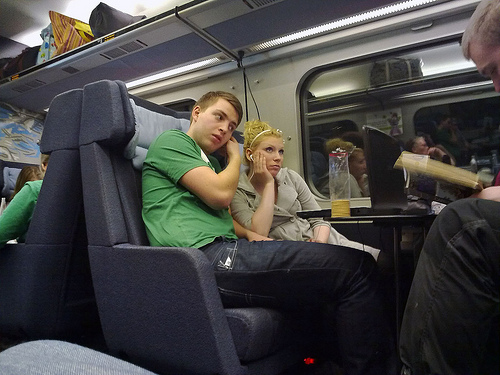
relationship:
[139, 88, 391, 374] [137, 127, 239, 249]
guy wearing shirt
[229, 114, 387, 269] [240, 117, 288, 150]
woman with hair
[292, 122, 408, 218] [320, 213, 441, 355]
laptop on table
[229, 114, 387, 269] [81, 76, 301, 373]
woman in seat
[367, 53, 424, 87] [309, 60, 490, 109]
duffle bag on shelf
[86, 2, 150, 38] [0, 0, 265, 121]
bag on shelf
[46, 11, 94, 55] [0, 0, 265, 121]
bag on shelf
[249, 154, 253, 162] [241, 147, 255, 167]
ear bud in ear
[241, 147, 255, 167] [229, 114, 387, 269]
ear of woman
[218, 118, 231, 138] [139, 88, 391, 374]
nose on guy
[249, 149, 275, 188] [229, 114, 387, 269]
right hand of woman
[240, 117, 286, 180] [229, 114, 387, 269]
head of woman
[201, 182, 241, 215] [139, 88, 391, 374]
right elbow of guy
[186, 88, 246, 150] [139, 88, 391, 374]
head of guy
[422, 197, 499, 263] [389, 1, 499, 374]
left knee of man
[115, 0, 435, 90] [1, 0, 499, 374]
overhead light on train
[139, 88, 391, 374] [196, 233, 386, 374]
guy wearing blue jeans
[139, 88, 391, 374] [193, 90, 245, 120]
guy has hair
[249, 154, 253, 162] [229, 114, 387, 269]
ear bud on woman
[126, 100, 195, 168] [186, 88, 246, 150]
cushion for head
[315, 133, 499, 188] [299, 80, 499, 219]
reflection in window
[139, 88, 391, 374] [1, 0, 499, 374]
guy on train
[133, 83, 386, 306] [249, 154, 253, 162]
couple sharing ear bud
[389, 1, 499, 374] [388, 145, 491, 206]
man reading book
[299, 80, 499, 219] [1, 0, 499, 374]
window on train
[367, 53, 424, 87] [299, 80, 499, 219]
duffle bag reflected in window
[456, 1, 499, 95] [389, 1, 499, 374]
head of man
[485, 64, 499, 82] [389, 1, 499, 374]
eye of man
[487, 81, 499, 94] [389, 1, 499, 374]
nose of man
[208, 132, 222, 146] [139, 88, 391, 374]
mouth of guy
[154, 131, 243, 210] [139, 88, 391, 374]
arm of guy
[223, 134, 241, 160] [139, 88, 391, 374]
hand of guy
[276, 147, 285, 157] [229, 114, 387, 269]
eye of woman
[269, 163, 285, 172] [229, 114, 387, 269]
mouth of woman